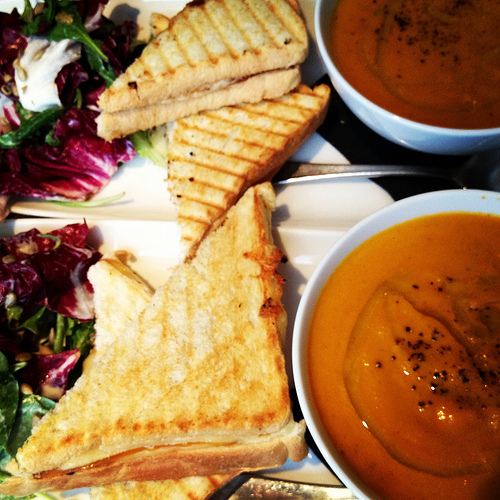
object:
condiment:
[370, 279, 500, 427]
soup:
[309, 213, 500, 500]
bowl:
[291, 189, 500, 500]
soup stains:
[481, 195, 485, 199]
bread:
[161, 84, 329, 263]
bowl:
[312, 1, 499, 155]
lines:
[165, 84, 328, 262]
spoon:
[277, 153, 429, 186]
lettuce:
[2, 111, 136, 202]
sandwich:
[0, 184, 307, 499]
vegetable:
[0, 220, 100, 395]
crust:
[282, 84, 327, 135]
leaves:
[1, 356, 56, 476]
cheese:
[161, 79, 236, 104]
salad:
[0, 0, 165, 199]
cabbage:
[4, 222, 100, 325]